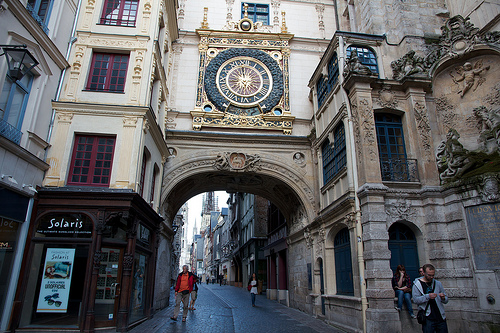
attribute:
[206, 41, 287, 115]
clock — part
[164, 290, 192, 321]
pants — khaki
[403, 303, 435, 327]
bag — black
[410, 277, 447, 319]
hoodie — gray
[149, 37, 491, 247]
building — elaborate 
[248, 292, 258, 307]
jeans — blue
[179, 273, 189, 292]
shirt — orange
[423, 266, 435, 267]
hair — short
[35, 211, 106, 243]
lettering — white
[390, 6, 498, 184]
design — elaborate 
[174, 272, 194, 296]
shirt — orange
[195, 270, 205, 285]
arm — part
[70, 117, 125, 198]
windows — red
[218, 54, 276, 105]
clock — black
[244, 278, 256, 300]
shirt — white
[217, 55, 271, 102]
numerals — gold, roman 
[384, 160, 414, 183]
gate — iron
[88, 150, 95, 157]
framing — red 